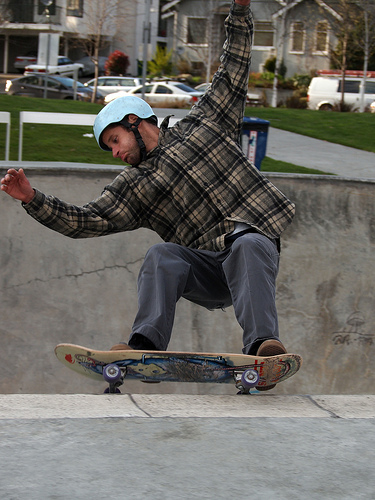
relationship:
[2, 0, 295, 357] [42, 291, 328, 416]
man on skateboard.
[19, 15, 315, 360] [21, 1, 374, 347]
man in park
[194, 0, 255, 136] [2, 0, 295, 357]
arm of man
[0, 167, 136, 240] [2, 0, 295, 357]
arm of man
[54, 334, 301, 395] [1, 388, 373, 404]
skateboard on edge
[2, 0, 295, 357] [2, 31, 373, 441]
man on ramp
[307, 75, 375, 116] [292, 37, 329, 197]
van parked on street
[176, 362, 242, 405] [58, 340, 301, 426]
bottom of skateboard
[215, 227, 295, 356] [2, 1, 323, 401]
leg of a man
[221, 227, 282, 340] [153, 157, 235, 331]
leg of a man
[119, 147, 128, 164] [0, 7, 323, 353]
mouth of a man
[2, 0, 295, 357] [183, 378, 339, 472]
man skateboarding on halfpipe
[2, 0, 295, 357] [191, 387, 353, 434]
man skateboarding on halfpipe